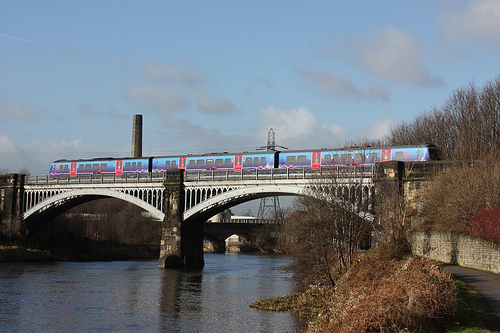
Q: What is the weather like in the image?
A: It is clear.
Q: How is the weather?
A: It is clear.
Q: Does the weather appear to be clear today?
A: Yes, it is clear.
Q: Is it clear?
A: Yes, it is clear.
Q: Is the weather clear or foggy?
A: It is clear.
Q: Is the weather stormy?
A: No, it is clear.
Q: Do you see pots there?
A: No, there are no pots.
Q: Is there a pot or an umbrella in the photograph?
A: No, there are no pots or umbrellas.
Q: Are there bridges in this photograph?
A: Yes, there is a bridge.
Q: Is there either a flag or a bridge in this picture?
A: Yes, there is a bridge.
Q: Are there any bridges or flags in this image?
A: Yes, there is a bridge.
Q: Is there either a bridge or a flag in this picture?
A: Yes, there is a bridge.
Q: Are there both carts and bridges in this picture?
A: No, there is a bridge but no carts.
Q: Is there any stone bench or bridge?
A: Yes, there is a stone bridge.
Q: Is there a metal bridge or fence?
A: Yes, there is a metal bridge.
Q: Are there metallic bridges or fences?
A: Yes, there is a metal bridge.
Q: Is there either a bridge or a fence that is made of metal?
A: Yes, the bridge is made of metal.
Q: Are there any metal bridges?
A: Yes, there is a metal bridge.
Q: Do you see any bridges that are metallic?
A: Yes, there is a metal bridge.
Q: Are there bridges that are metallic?
A: Yes, there is a bridge that is metallic.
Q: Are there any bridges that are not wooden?
A: Yes, there is a metallic bridge.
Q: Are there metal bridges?
A: Yes, there is a bridge that is made of metal.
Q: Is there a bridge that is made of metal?
A: Yes, there is a bridge that is made of metal.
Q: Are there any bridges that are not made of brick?
A: Yes, there is a bridge that is made of metal.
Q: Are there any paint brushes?
A: No, there are no paint brushes.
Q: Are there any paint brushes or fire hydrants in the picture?
A: No, there are no paint brushes or fire hydrants.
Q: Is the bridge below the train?
A: Yes, the bridge is below the train.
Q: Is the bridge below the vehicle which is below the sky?
A: Yes, the bridge is below the train.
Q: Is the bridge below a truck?
A: No, the bridge is below the train.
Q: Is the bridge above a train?
A: No, the bridge is below a train.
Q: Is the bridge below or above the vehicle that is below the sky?
A: The bridge is below the train.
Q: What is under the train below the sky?
A: The bridge is under the train.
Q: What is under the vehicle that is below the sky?
A: The bridge is under the train.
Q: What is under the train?
A: The bridge is under the train.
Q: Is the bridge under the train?
A: Yes, the bridge is under the train.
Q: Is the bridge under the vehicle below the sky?
A: Yes, the bridge is under the train.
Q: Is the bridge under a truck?
A: No, the bridge is under the train.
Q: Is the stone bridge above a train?
A: No, the bridge is under a train.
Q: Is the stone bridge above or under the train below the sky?
A: The bridge is under the train.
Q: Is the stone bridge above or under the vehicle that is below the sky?
A: The bridge is under the train.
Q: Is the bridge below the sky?
A: Yes, the bridge is below the sky.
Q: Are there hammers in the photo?
A: No, there are no hammers.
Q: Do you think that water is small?
A: Yes, the water is small.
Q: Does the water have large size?
A: No, the water is small.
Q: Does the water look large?
A: No, the water is small.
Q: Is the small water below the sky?
A: Yes, the water is below the sky.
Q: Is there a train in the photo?
A: Yes, there is a train.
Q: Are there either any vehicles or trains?
A: Yes, there is a train.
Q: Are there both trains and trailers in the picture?
A: No, there is a train but no trailers.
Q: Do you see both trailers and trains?
A: No, there is a train but no trailers.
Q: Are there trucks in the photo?
A: No, there are no trucks.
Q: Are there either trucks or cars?
A: No, there are no trucks or cars.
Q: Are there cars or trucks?
A: No, there are no trucks or cars.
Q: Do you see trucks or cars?
A: No, there are no trucks or cars.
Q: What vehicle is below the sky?
A: The vehicle is a train.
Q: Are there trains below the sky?
A: Yes, there is a train below the sky.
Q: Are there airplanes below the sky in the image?
A: No, there is a train below the sky.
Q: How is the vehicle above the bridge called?
A: The vehicle is a train.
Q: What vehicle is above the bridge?
A: The vehicle is a train.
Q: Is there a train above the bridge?
A: Yes, there is a train above the bridge.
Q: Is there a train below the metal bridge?
A: No, the train is above the bridge.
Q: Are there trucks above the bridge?
A: No, there is a train above the bridge.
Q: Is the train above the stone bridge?
A: Yes, the train is above the bridge.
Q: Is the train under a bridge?
A: No, the train is above a bridge.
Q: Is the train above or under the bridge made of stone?
A: The train is above the bridge.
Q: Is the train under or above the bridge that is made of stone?
A: The train is above the bridge.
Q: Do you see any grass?
A: Yes, there is grass.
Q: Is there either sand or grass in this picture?
A: Yes, there is grass.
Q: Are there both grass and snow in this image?
A: No, there is grass but no snow.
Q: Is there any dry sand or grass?
A: Yes, there is dry grass.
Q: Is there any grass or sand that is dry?
A: Yes, the grass is dry.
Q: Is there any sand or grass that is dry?
A: Yes, the grass is dry.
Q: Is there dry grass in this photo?
A: Yes, there is dry grass.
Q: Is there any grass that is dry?
A: Yes, there is grass that is dry.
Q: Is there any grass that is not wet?
A: Yes, there is dry grass.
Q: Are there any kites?
A: No, there are no kites.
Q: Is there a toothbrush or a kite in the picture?
A: No, there are no kites or toothbrushes.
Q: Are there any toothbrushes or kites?
A: No, there are no kites or toothbrushes.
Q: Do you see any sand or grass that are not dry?
A: No, there is grass but it is dry.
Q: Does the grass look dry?
A: Yes, the grass is dry.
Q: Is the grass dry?
A: Yes, the grass is dry.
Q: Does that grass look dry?
A: Yes, the grass is dry.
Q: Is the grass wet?
A: No, the grass is dry.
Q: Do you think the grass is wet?
A: No, the grass is dry.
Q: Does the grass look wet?
A: No, the grass is dry.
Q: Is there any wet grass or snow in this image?
A: No, there is grass but it is dry.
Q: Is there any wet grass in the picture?
A: No, there is grass but it is dry.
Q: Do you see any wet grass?
A: No, there is grass but it is dry.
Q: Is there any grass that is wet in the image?
A: No, there is grass but it is dry.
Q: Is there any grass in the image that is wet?
A: No, there is grass but it is dry.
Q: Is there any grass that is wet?
A: No, there is grass but it is dry.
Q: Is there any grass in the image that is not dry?
A: No, there is grass but it is dry.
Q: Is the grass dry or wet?
A: The grass is dry.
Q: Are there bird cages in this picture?
A: No, there are no bird cages.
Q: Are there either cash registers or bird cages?
A: No, there are no bird cages or cash registers.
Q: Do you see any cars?
A: No, there are no cars.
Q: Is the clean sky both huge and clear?
A: Yes, the sky is huge and clear.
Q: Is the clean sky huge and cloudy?
A: No, the sky is huge but clear.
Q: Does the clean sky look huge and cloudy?
A: No, the sky is huge but clear.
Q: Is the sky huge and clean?
A: Yes, the sky is huge and clean.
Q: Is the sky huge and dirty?
A: No, the sky is huge but clean.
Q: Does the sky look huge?
A: Yes, the sky is huge.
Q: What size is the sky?
A: The sky is huge.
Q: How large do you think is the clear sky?
A: The sky is huge.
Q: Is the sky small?
A: No, the sky is huge.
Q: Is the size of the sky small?
A: No, the sky is huge.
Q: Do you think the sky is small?
A: No, the sky is huge.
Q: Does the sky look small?
A: No, the sky is huge.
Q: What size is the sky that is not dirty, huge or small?
A: The sky is huge.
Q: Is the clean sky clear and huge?
A: Yes, the sky is clear and huge.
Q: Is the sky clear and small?
A: No, the sky is clear but huge.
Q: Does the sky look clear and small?
A: No, the sky is clear but huge.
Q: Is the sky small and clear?
A: No, the sky is clear but huge.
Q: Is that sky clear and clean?
A: Yes, the sky is clear and clean.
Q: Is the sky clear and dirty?
A: No, the sky is clear but clean.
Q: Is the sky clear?
A: Yes, the sky is clear.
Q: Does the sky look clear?
A: Yes, the sky is clear.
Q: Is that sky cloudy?
A: No, the sky is clear.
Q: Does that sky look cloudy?
A: No, the sky is clear.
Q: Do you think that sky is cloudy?
A: No, the sky is clear.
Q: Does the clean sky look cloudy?
A: No, the sky is clear.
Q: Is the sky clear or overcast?
A: The sky is clear.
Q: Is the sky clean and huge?
A: Yes, the sky is clean and huge.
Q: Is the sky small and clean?
A: No, the sky is clean but huge.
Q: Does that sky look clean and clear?
A: Yes, the sky is clean and clear.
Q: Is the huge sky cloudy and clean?
A: No, the sky is clean but clear.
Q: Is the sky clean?
A: Yes, the sky is clean.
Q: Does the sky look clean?
A: Yes, the sky is clean.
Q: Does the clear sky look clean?
A: Yes, the sky is clean.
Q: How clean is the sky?
A: The sky is clean.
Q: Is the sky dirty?
A: No, the sky is clean.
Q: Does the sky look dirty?
A: No, the sky is clean.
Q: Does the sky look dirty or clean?
A: The sky is clean.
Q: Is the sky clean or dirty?
A: The sky is clean.